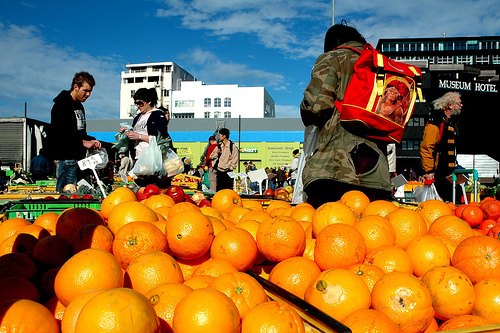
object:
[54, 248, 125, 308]
oranges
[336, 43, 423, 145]
book bag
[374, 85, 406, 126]
character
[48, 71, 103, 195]
man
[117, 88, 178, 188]
woman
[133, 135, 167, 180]
bags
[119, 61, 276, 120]
building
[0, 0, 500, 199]
background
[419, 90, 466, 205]
man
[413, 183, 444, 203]
bags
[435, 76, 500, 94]
sign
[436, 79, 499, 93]
museum hotel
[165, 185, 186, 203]
apples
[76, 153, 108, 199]
sign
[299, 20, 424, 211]
man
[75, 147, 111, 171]
bag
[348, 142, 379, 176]
hole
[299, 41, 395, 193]
jacket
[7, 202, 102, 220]
cartons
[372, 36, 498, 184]
hotel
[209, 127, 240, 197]
man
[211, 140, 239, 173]
jacket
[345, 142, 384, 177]
patch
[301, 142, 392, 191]
bottom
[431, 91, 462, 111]
hair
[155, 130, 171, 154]
purse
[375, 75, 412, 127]
decal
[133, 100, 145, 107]
sunglasses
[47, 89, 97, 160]
sweater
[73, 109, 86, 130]
design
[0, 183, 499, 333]
pile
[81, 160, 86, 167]
number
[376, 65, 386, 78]
snap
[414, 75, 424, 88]
snap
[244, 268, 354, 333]
baskets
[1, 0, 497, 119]
sky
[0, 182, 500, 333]
produce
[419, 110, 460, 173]
jacket